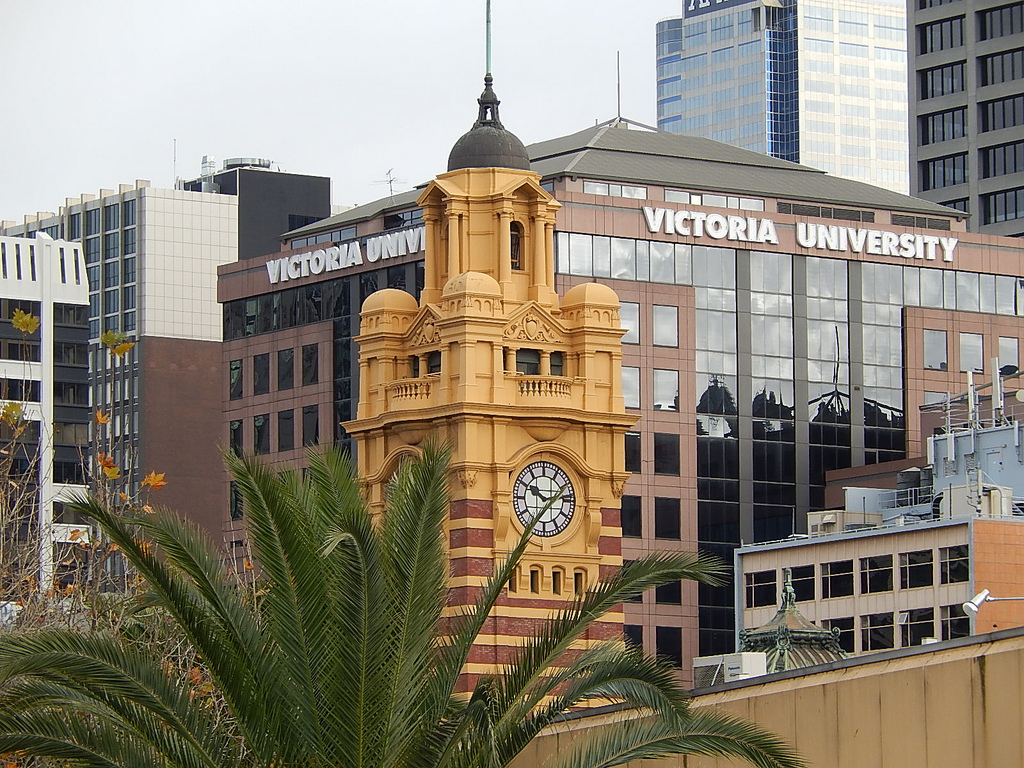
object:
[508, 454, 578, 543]
clock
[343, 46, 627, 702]
tower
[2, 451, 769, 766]
tree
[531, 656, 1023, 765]
building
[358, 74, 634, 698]
building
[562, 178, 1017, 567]
building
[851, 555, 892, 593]
windows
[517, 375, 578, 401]
balcony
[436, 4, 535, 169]
steeple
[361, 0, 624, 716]
tower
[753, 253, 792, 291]
window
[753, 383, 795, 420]
window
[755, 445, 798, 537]
window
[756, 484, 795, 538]
window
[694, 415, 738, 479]
window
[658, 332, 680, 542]
window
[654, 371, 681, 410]
window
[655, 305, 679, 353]
window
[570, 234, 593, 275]
window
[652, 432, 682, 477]
window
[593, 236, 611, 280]
window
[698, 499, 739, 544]
window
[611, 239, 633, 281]
window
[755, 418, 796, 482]
window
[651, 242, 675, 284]
window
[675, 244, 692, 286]
window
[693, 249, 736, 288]
window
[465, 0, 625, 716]
side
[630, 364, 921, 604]
reflection